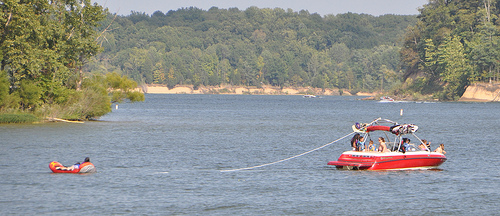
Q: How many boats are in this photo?
A: 1.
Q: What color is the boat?
A: Red.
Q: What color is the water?
A: Blue.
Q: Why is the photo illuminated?
A: It is daylight.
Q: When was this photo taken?
A: During the day.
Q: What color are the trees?
A: Green.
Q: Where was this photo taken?
A: On the water.